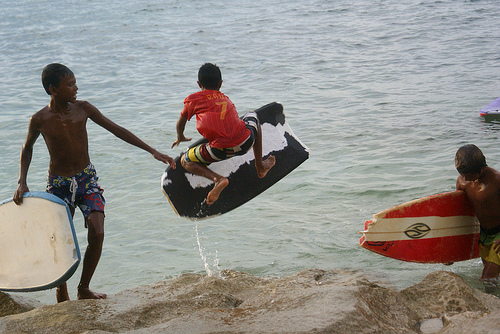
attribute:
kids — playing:
[15, 63, 179, 300]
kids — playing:
[177, 64, 276, 203]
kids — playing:
[455, 144, 499, 277]